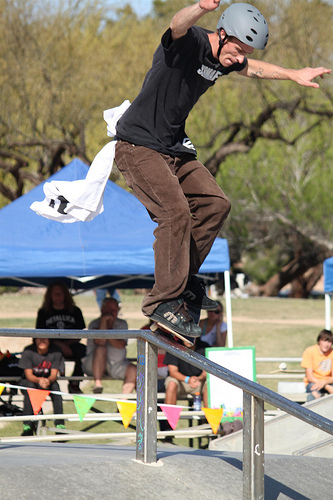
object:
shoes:
[147, 275, 219, 340]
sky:
[0, 0, 332, 36]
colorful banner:
[1, 380, 225, 435]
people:
[0, 263, 332, 435]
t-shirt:
[115, 26, 248, 157]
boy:
[299, 328, 332, 399]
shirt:
[299, 344, 332, 385]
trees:
[0, 0, 332, 297]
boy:
[102, 1, 332, 351]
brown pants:
[112, 130, 233, 317]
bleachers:
[0, 273, 229, 455]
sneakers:
[140, 280, 217, 337]